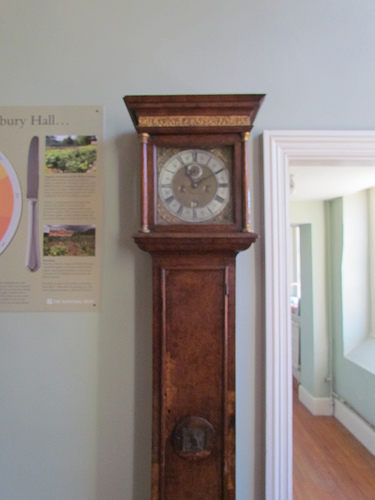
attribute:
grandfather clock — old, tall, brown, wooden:
[117, 93, 264, 499]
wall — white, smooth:
[11, 92, 262, 499]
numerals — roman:
[161, 155, 229, 223]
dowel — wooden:
[141, 132, 159, 236]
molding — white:
[261, 129, 299, 401]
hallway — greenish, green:
[294, 171, 363, 496]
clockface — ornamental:
[154, 145, 232, 219]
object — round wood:
[165, 416, 214, 463]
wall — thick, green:
[308, 234, 372, 445]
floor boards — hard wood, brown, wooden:
[292, 390, 367, 500]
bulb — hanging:
[300, 175, 364, 214]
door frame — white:
[260, 127, 374, 498]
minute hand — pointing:
[196, 167, 227, 180]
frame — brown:
[130, 93, 259, 253]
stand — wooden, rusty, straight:
[141, 232, 253, 499]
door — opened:
[266, 132, 374, 499]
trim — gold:
[141, 115, 254, 131]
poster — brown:
[2, 108, 107, 323]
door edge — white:
[261, 128, 363, 194]